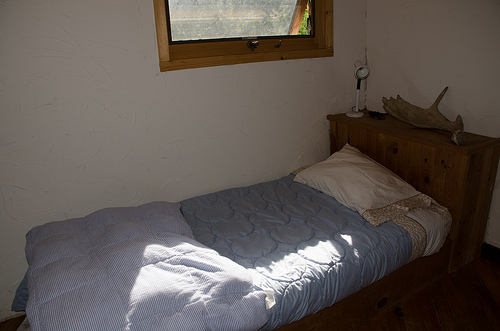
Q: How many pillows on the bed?
A: One.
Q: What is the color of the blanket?
A: Blue.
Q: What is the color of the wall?
A: Beige.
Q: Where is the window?
A: At the side of the bed.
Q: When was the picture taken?
A: Daytime.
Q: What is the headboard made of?
A: Wood.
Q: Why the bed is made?
A: To make it presentable.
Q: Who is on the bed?
A: No one.